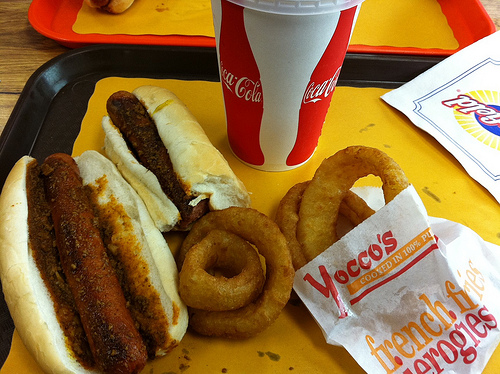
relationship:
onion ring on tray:
[186, 228, 267, 312] [8, 40, 498, 353]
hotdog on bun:
[42, 148, 156, 372] [67, 146, 204, 368]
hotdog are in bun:
[37, 153, 156, 374] [67, 146, 204, 368]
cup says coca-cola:
[199, 3, 366, 171] [214, 53, 266, 107]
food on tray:
[27, 89, 383, 313] [8, 40, 498, 353]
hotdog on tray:
[42, 148, 156, 372] [8, 40, 498, 353]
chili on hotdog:
[25, 189, 67, 267] [42, 148, 156, 372]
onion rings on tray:
[170, 202, 299, 338] [8, 40, 498, 353]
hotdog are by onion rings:
[37, 153, 156, 374] [170, 202, 299, 338]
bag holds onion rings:
[307, 185, 490, 369] [274, 140, 410, 243]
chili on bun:
[25, 189, 67, 267] [67, 146, 204, 368]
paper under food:
[344, 76, 395, 143] [27, 89, 383, 313]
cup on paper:
[199, 3, 366, 171] [344, 76, 395, 143]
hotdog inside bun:
[42, 148, 156, 372] [67, 146, 204, 368]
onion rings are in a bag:
[274, 140, 410, 243] [307, 185, 490, 369]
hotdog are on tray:
[37, 153, 156, 374] [8, 40, 498, 353]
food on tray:
[0, 84, 412, 374] [8, 40, 498, 353]